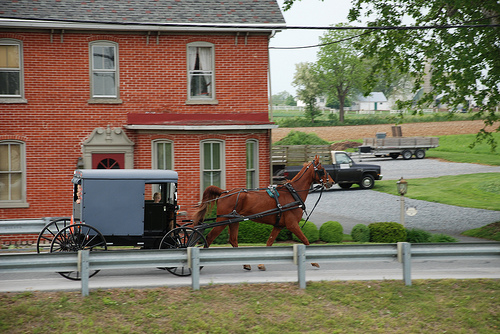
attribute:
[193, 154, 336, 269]
horse — brown, walking, trotting, moving, cute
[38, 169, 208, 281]
buggy — grey, gray, old fashioned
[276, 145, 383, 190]
truck — black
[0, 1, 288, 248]
building — large, brick, red, black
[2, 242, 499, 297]
rail — grey, white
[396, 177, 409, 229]
light — off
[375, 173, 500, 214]
grass — green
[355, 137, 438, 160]
trailer — parked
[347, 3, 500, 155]
tree — hanging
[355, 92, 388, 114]
house — far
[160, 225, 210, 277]
wheel — wood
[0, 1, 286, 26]
roof — shingled